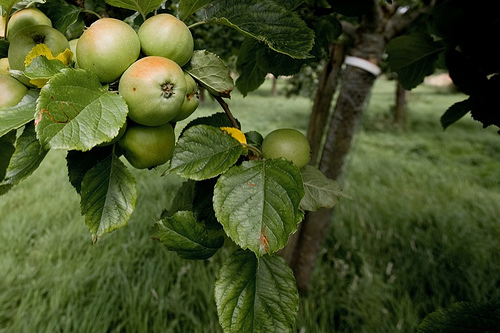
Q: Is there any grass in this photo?
A: Yes, there is grass.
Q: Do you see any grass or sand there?
A: Yes, there is grass.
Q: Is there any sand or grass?
A: Yes, there is grass.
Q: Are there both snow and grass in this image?
A: No, there is grass but no snow.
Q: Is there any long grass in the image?
A: Yes, there is long grass.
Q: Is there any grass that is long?
A: Yes, there is grass that is long.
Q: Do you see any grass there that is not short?
A: Yes, there is long grass.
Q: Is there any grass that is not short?
A: Yes, there is long grass.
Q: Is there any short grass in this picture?
A: Yes, there is short grass.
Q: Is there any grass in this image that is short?
A: Yes, there is grass that is short.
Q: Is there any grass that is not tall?
A: Yes, there is short grass.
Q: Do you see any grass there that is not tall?
A: Yes, there is short grass.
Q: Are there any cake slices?
A: No, there are no cake slices.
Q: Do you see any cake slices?
A: No, there are no cake slices.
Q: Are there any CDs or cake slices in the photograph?
A: No, there are no cake slices or cds.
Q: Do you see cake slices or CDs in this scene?
A: No, there are no cake slices or cds.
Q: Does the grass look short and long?
A: Yes, the grass is short and long.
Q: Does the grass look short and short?
A: No, the grass is short but long.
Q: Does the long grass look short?
A: Yes, the grass is short.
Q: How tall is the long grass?
A: The grass is short.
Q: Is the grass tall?
A: No, the grass is short.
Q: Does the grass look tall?
A: No, the grass is short.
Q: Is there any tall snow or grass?
A: No, there is grass but it is short.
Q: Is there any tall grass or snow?
A: No, there is grass but it is short.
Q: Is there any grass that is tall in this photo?
A: No, there is grass but it is short.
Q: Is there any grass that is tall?
A: No, there is grass but it is short.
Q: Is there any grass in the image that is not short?
A: No, there is grass but it is short.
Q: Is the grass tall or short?
A: The grass is short.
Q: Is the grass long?
A: Yes, the grass is long.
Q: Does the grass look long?
A: Yes, the grass is long.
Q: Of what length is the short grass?
A: The grass is long.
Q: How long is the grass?
A: The grass is long.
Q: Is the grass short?
A: No, the grass is long.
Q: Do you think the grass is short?
A: No, the grass is long.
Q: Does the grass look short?
A: No, the grass is long.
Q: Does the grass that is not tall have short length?
A: No, the grass is long.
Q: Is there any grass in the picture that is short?
A: No, there is grass but it is long.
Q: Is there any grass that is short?
A: No, there is grass but it is long.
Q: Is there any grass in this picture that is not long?
A: No, there is grass but it is long.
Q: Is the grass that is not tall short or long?
A: The grass is long.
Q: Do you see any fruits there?
A: Yes, there is a fruit.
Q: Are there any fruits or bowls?
A: Yes, there is a fruit.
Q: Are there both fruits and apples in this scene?
A: Yes, there are both a fruit and an apple.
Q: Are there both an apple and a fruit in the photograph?
A: Yes, there are both a fruit and an apple.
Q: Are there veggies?
A: No, there are no veggies.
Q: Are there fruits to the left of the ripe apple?
A: Yes, there is a fruit to the left of the apple.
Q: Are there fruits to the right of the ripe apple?
A: No, the fruit is to the left of the apple.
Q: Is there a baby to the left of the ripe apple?
A: No, there is a fruit to the left of the apple.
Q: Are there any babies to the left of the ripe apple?
A: No, there is a fruit to the left of the apple.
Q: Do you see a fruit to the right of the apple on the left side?
A: Yes, there is a fruit to the right of the apple.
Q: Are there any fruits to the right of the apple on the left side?
A: Yes, there is a fruit to the right of the apple.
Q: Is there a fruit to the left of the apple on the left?
A: No, the fruit is to the right of the apple.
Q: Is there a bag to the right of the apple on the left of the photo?
A: No, there is a fruit to the right of the apple.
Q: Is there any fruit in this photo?
A: Yes, there is a fruit.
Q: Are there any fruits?
A: Yes, there is a fruit.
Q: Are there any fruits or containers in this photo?
A: Yes, there is a fruit.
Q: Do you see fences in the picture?
A: No, there are no fences.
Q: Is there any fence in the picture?
A: No, there are no fences.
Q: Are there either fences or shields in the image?
A: No, there are no fences or shields.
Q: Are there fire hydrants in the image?
A: No, there are no fire hydrants.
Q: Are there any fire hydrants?
A: No, there are no fire hydrants.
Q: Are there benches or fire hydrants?
A: No, there are no fire hydrants or benches.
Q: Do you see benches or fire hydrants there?
A: No, there are no fire hydrants or benches.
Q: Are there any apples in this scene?
A: Yes, there is an apple.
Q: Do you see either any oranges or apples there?
A: Yes, there is an apple.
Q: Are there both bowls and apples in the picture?
A: No, there is an apple but no bowls.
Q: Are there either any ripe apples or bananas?
A: Yes, there is a ripe apple.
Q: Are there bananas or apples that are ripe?
A: Yes, the apple is ripe.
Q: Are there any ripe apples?
A: Yes, there is a ripe apple.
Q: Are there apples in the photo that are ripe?
A: Yes, there is an apple that is ripe.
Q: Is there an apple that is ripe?
A: Yes, there is an apple that is ripe.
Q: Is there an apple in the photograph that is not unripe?
A: Yes, there is an ripe apple.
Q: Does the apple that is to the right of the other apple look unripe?
A: No, the apple is ripe.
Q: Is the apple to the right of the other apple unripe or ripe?
A: The apple is ripe.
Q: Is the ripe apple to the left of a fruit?
A: No, the apple is to the right of a fruit.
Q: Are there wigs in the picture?
A: No, there are no wigs.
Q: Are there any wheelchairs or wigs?
A: No, there are no wigs or wheelchairs.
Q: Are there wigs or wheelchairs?
A: No, there are no wigs or wheelchairs.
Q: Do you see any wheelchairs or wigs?
A: No, there are no wigs or wheelchairs.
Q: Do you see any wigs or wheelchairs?
A: No, there are no wigs or wheelchairs.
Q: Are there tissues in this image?
A: No, there are no tissues.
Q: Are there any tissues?
A: No, there are no tissues.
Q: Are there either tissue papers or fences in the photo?
A: No, there are no tissue papers or fences.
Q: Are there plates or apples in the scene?
A: Yes, there is an apple.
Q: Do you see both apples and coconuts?
A: No, there is an apple but no coconuts.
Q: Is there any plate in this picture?
A: No, there are no plates.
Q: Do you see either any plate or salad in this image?
A: No, there are no plates or salad.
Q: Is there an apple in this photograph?
A: Yes, there is an apple.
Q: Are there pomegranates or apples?
A: Yes, there is an apple.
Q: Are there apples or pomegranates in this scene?
A: Yes, there is an apple.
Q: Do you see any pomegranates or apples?
A: Yes, there is an apple.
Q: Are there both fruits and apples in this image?
A: Yes, there are both an apple and a fruit.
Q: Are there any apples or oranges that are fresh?
A: Yes, the apple is fresh.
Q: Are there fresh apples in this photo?
A: Yes, there is a fresh apple.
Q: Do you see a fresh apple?
A: Yes, there is a fresh apple.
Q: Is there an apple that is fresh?
A: Yes, there is an apple that is fresh.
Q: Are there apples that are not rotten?
A: Yes, there is a fresh apple.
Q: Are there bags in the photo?
A: No, there are no bags.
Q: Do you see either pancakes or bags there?
A: No, there are no bags or pancakes.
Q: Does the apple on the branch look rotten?
A: No, the apple is fresh.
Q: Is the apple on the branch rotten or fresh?
A: The apple is fresh.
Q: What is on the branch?
A: The apple is on the branch.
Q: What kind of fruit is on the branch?
A: The fruit is an apple.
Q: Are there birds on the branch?
A: No, there is an apple on the branch.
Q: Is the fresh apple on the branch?
A: Yes, the apple is on the branch.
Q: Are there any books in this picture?
A: No, there are no books.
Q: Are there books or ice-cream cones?
A: No, there are no books or ice-cream cones.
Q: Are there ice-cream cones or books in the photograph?
A: No, there are no books or ice-cream cones.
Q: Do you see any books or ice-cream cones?
A: No, there are no books or ice-cream cones.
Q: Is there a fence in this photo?
A: No, there are no fences.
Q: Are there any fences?
A: No, there are no fences.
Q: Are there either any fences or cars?
A: No, there are no fences or cars.